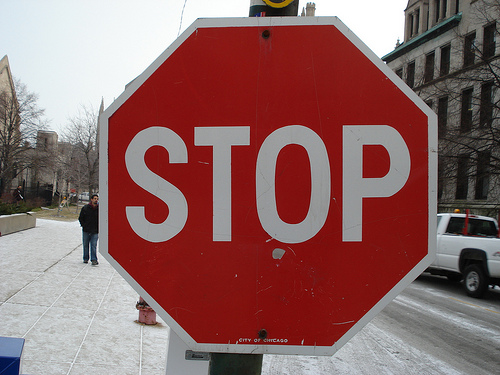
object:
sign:
[97, 16, 440, 356]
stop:
[119, 123, 411, 243]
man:
[75, 193, 98, 265]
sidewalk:
[0, 217, 172, 375]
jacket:
[78, 203, 104, 235]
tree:
[55, 98, 102, 206]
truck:
[420, 207, 500, 297]